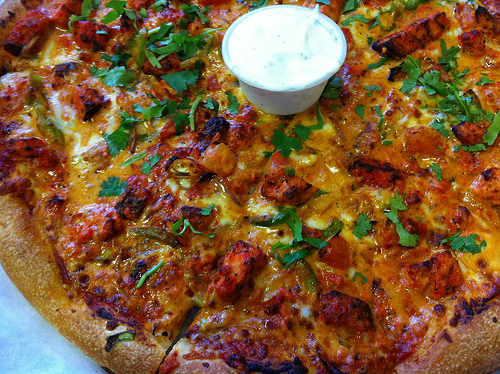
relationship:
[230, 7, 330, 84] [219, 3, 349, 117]
dip in container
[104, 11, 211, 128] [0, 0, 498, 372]
chopped parsley on pizza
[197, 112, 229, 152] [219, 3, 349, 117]
burnt piece near container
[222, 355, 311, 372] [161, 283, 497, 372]
burn area on crust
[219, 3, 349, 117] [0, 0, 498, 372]
container on top of pizza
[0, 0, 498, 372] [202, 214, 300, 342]
pizza covered with red sauce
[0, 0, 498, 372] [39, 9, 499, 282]
pizza covered with cheese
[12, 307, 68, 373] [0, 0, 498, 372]
white thing under pizza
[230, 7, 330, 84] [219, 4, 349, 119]
dip in bowl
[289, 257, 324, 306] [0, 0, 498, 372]
green thing on pizza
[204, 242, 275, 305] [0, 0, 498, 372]
sauce on pizza